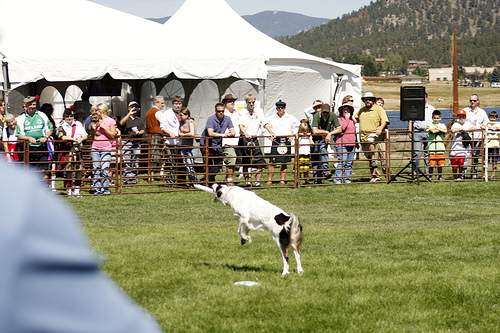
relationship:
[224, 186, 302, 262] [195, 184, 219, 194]
dog catching frisbee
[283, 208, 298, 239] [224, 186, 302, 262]
tail of dog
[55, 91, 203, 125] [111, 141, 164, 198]
people behind fence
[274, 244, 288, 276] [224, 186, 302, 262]
leg of dog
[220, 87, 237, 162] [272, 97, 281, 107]
man wearing hat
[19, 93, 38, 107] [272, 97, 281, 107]
woman wearing hat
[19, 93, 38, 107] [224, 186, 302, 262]
woman holding dog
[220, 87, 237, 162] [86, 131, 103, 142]
man wearing shirt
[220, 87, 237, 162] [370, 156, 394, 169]
man wearing kilt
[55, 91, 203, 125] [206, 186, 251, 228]
people watching goat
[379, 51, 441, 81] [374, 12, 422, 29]
houses on mountain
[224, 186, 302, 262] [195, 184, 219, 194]
dog catches frisbee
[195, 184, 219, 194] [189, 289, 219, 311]
frisbee on ground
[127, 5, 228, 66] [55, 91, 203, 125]
tent behind people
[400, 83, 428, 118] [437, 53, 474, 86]
speaker on pole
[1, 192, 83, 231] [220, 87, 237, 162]
shoulder of man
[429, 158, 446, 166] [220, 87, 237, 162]
shorts of man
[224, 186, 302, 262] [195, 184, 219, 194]
dog caught frisbee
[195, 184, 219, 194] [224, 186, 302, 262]
frisbee of dog